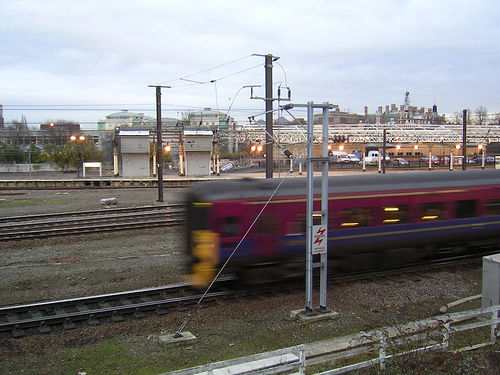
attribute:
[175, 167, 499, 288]
train — yellow, red, blue, red ,blue, grey, purple, moving very fast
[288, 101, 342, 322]
pole — metal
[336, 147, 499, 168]
cars — parked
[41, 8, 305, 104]
clouds — minor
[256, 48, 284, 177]
electrical pole — tall, wooden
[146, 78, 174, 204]
electrical pole — tall, wooden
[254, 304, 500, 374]
fence — white, small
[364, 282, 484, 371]
bush — small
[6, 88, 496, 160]
buildings — in background, in distance, large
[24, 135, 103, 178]
trees — small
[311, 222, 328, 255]
sign — white, for danger, indicating hazard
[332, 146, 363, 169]
vans — parked, white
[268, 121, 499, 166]
building — brick, square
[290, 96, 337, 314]
utility pole — grey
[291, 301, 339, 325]
footer — concrete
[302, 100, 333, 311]
posts — metal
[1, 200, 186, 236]
train tracks — in a line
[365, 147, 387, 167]
vehicle — white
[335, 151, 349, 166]
vehicle — white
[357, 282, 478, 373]
shrub — green, small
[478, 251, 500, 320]
box — metal, gray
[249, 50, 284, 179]
utility pole — brown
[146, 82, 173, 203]
utility pole — brown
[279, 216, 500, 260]
stripe — blue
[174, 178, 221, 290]
front — yellow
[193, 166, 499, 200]
top — gray